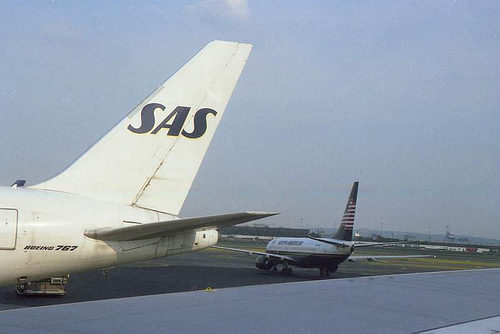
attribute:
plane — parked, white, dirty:
[0, 39, 281, 301]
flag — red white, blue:
[341, 202, 356, 232]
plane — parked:
[214, 182, 439, 280]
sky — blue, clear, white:
[0, 1, 497, 244]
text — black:
[127, 99, 218, 140]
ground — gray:
[1, 225, 497, 332]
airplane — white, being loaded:
[0, 40, 284, 296]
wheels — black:
[272, 266, 294, 277]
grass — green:
[183, 235, 499, 273]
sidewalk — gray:
[0, 268, 499, 333]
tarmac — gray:
[1, 250, 446, 327]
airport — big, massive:
[1, 2, 498, 334]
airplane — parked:
[208, 180, 361, 279]